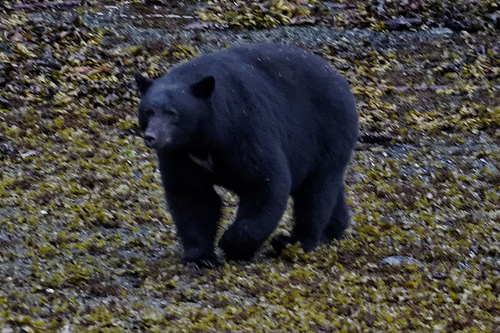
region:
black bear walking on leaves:
[128, 35, 388, 272]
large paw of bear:
[219, 217, 279, 271]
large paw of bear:
[185, 219, 223, 269]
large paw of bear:
[290, 205, 327, 242]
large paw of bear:
[326, 205, 353, 234]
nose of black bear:
[136, 124, 168, 143]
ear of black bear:
[178, 69, 221, 101]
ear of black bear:
[133, 81, 162, 101]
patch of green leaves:
[80, 230, 115, 261]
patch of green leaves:
[100, 300, 146, 321]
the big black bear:
[131, 40, 354, 265]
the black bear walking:
[131, 38, 357, 268]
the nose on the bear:
[140, 130, 155, 145]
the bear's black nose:
[140, 130, 150, 140]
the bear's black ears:
[130, 65, 212, 90]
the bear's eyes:
[145, 105, 176, 115]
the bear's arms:
[146, 165, 286, 265]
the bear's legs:
[291, 160, 348, 253]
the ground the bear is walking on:
[111, 265, 436, 327]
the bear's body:
[218, 42, 358, 162]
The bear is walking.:
[117, 32, 396, 277]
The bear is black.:
[112, 25, 399, 284]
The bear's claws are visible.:
[168, 247, 223, 275]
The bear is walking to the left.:
[107, 25, 415, 286]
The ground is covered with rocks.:
[350, 223, 473, 293]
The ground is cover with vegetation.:
[0, 255, 497, 331]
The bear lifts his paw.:
[207, 142, 304, 272]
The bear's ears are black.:
[125, 59, 236, 96]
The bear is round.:
[127, 27, 412, 276]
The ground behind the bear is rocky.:
[45, 16, 463, 61]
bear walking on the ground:
[117, 45, 388, 290]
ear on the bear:
[188, 71, 225, 101]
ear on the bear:
[130, 62, 157, 97]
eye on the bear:
[163, 97, 186, 127]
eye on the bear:
[141, 101, 155, 121]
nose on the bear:
[141, 125, 166, 155]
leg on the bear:
[228, 190, 277, 289]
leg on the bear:
[160, 177, 209, 261]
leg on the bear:
[302, 172, 337, 255]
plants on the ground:
[310, 272, 387, 321]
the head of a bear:
[128, 62, 221, 156]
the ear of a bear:
[187, 69, 220, 102]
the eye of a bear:
[161, 103, 181, 119]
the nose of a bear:
[140, 126, 159, 148]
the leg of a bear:
[226, 150, 296, 240]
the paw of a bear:
[176, 240, 222, 277]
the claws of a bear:
[183, 252, 226, 272]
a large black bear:
[126, 42, 369, 272]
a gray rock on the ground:
[378, 250, 425, 277]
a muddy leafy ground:
[1, 0, 497, 330]